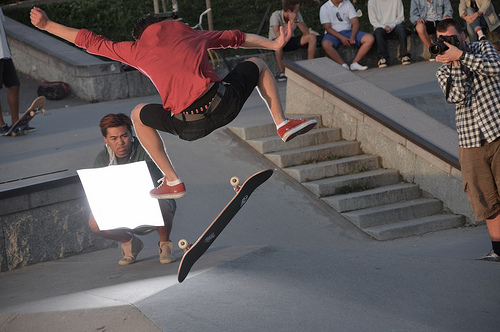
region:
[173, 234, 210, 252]
white wheels on bottom of skate board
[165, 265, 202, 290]
black edge of skate board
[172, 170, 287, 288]
skate board levitating in the air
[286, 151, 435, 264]
gray stone steps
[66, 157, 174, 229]
man holding white paper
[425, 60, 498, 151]
black and white plaid shirt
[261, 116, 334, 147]
red and white sneakers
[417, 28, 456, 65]
black camera in man's hand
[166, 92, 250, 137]
gray belt in black shorts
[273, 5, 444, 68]
people sitting on stoop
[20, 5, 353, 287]
A person is flying through the air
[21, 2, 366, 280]
A person is doing a skateboard stunt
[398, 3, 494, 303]
A person is using his camera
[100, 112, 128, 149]
The head of a person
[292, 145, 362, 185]
The steps in a skateboarding area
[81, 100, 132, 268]
A man is crouching and holding something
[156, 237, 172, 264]
A shoe on somebody's foot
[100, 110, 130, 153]
A person with dark colored hair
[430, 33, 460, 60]
A hand holding a camera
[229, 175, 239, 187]
The wheel of a skateboard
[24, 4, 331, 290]
a skater jumps in the air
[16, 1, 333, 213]
skater has extended arms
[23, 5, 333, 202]
skater wears a red top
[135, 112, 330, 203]
a pair of tennis shoes in the air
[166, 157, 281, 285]
a skateboard is upside down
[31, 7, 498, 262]
a man taking a picture to skater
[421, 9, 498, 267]
man holding a black camera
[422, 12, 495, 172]
man wears a squared shirt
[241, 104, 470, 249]
stairs of concrete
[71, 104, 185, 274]
man holding a mirror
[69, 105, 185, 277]
a person holding a mirror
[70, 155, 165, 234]
mirror reflects light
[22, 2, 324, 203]
skater in the air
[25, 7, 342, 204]
skater is crouched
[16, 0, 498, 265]
man taking picture to skater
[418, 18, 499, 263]
man has a camera in front his face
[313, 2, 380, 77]
person wears a white short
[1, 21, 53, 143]
person raise a skateboard with right feet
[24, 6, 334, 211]
skater wears a red long sleeve shirt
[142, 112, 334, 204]
pair of red shoes with white sole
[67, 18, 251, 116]
Person is wearing a red shirt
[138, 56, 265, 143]
Person is wearing black shorts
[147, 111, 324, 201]
Person is wearing white socks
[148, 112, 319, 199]
Person is wearing red and white shoes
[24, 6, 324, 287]
Person is doing a trick on a skateboard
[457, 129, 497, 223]
Man is wearing brown shorts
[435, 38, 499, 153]
Man is wearing black and white checkered shirt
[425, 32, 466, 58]
Man is holding a camera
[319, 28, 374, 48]
Man is wearing blue shorts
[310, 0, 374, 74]
Man is sitting down